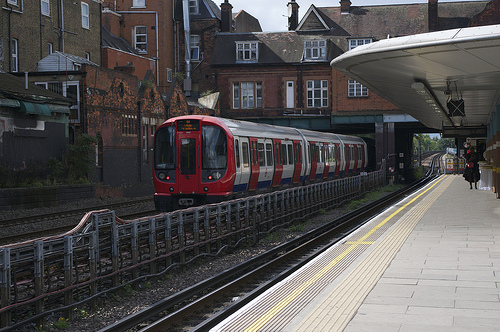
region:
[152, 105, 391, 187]
red metro train at station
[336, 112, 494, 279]
boarding platform on right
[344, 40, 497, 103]
overhang of boarding platform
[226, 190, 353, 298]
second set of train tracks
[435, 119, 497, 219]
passengers waiting on platform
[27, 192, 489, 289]
small fence between tracks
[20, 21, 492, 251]
multi story buildings around tracks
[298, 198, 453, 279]
yellow line by tracks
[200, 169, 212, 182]
red headlight on train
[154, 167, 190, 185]
red headlight on train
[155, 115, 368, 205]
Red, white and blue train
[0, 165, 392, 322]
Guard rails between tracks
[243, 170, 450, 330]
Yellow warning line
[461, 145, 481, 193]
Person waiting for train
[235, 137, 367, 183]
White doors on the train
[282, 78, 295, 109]
Narrow white door with black window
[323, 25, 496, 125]
Roof over waiting area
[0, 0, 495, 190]
Stone and brick buidlings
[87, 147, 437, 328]
Empty train track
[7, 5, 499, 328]
A beautiful train station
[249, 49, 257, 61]
window on side of building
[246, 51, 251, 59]
window on side of building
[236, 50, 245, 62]
window on side of building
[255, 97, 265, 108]
window on side of building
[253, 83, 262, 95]
window on side of building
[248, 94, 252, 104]
window on side of building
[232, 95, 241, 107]
window on side of building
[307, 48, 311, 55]
window on side of building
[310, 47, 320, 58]
window on side of building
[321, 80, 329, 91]
window on side of building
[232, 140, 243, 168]
window on side of train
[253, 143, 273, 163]
window on side of train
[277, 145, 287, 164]
window on side of train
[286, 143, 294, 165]
window on side of train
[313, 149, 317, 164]
window on side of train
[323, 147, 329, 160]
window on side of train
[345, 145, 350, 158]
window on side of train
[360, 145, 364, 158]
window on side of train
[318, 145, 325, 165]
window on side of train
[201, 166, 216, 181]
a red light on the train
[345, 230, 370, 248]
yellow line painted on the ground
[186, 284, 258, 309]
a track for a train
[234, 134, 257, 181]
a door on the train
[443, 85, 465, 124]
a sign with a letter on it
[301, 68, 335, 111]
windows on a building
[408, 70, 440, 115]
lights on the ceiling of the building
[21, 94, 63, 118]
a canopy over a window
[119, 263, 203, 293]
gravel between the train tracks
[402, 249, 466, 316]
a tile walkway in the station